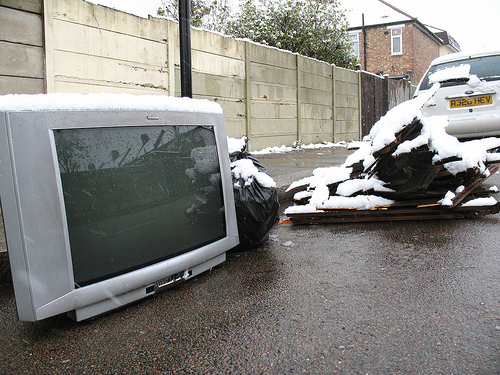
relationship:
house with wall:
[350, 11, 468, 94] [356, 23, 408, 80]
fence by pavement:
[59, 19, 325, 139] [238, 150, 404, 280]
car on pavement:
[402, 47, 497, 131] [268, 219, 465, 347]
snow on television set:
[3, 88, 227, 116] [0, 107, 241, 325]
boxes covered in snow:
[281, 92, 499, 216] [359, 88, 429, 153]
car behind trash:
[411, 49, 499, 142] [2, 43, 482, 341]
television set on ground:
[1, 96, 239, 330] [1, 147, 499, 370]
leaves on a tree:
[153, 2, 356, 72] [155, 5, 369, 75]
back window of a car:
[413, 53, 498, 82] [417, 47, 498, 141]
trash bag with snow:
[222, 127, 298, 263] [222, 127, 278, 190]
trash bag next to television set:
[222, 136, 283, 253] [0, 107, 241, 325]